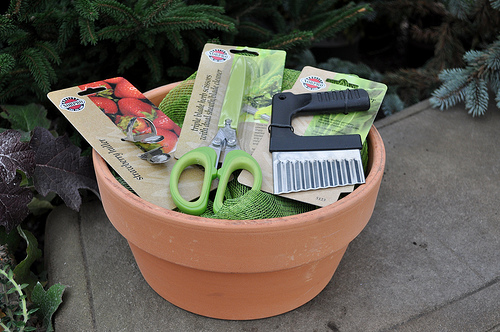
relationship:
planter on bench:
[93, 79, 387, 322] [44, 82, 499, 331]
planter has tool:
[93, 79, 387, 322] [270, 90, 371, 198]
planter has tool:
[93, 79, 387, 322] [168, 53, 261, 218]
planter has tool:
[93, 79, 387, 322] [44, 77, 234, 212]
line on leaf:
[40, 143, 71, 163] [26, 126, 100, 212]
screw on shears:
[212, 138, 222, 148] [168, 53, 261, 218]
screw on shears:
[226, 137, 236, 147] [168, 53, 261, 218]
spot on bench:
[404, 234, 442, 274] [44, 82, 499, 331]